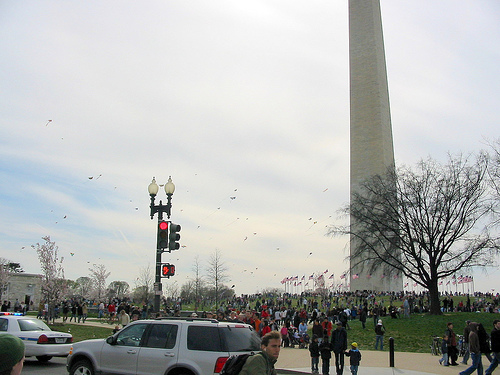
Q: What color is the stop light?
A: Red.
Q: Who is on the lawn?
A: A crowd of people.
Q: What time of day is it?
A: Daytime.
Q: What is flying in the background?
A: Flags.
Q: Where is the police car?
A: In front of the SUV.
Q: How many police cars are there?
A: One.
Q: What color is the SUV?
A: White.